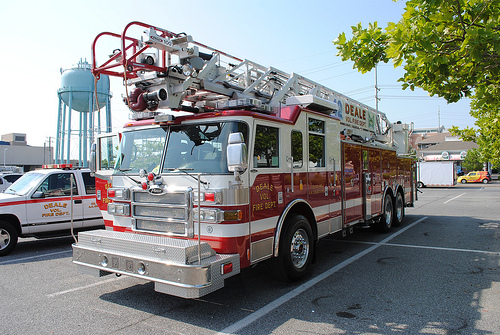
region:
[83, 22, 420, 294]
A red and white fire truck.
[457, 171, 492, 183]
A yellow and orange parked vehicle.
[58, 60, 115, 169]
A large green water tower.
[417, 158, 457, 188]
A white trailer.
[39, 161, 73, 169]
A white and red siren on top of a vehicle.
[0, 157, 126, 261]
A fire department vehicle.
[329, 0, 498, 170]
Part of a green leafy tree.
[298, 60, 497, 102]
Power lines.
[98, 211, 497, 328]
A shadow on the ground.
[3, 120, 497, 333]
Parked vehicles in a lot.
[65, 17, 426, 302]
The firetruck is parked.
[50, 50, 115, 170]
The water tower is blue.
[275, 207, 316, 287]
The tire is black.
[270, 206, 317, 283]
The tire is round.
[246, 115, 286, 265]
Orange lettering on firetruck door.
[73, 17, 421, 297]
The firetruck is red and white.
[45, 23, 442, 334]
The firetruck is using two parking spots.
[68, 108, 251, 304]
The front bumper is chrome.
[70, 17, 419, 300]
The firetruck ladder is down.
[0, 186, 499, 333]
Painted white lines in parking lot.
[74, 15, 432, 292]
the fire truck in the parking lot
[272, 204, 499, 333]
the shadow of the fire truck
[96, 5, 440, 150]
the ladder on the fire truck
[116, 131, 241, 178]
the windshield of the fire truck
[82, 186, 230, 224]
the lights on the fire truck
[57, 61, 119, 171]
the water tower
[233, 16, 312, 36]
the clear blue sky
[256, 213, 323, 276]
the front tire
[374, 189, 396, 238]
the rear tire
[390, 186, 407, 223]
the rear tire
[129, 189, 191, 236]
silver exhaust grill of truck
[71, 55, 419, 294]
Red fire engine parked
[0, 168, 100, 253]
fire chief vehicle parked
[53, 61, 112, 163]
blue water tower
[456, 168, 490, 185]
yellow and orange suv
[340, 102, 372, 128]
name of fire department printed on truck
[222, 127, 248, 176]
drivers side mirror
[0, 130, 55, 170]
tan building behind trucks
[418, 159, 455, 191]
white portable trailer behind truck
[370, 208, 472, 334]
shadow of fire truck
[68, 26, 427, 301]
Red and white fire truck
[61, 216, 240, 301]
Silver box in front of the fire truck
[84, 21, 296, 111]
Red and silver rails on ladder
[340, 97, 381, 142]
Red writing on side of truck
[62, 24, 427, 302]
The fire truck is parked on asphalt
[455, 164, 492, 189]
Yellow and orange car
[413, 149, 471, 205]
White trailer in the parking lot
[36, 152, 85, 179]
Red and white sirens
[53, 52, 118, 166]
Large water tower behind fire truck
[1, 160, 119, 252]
Truck with blue and red stripes